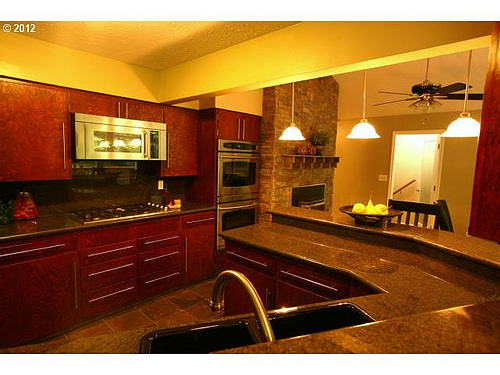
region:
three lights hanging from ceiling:
[282, 83, 490, 143]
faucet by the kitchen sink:
[211, 257, 283, 334]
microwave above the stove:
[65, 106, 177, 161]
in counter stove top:
[63, 198, 195, 223]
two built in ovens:
[195, 139, 263, 251]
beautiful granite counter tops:
[259, 222, 383, 260]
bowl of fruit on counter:
[343, 195, 408, 226]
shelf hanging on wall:
[285, 154, 355, 174]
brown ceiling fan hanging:
[379, 82, 484, 115]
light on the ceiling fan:
[407, 95, 442, 124]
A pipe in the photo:
[208, 268, 275, 336]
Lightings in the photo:
[344, 78, 380, 143]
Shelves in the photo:
[290, 209, 380, 259]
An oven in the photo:
[210, 139, 261, 223]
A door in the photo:
[393, 139, 437, 223]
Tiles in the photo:
[148, 287, 207, 322]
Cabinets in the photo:
[123, 229, 180, 286]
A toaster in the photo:
[8, 186, 41, 223]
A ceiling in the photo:
[160, 23, 227, 74]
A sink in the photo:
[152, 284, 356, 353]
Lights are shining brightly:
[278, 120, 479, 138]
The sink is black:
[147, 302, 372, 354]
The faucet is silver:
[209, 268, 271, 341]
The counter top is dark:
[387, 256, 452, 301]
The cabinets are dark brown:
[6, 209, 215, 342]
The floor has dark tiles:
[110, 282, 224, 331]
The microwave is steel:
[71, 112, 165, 159]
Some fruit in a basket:
[338, 195, 400, 225]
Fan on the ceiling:
[372, 80, 482, 113]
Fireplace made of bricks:
[257, 74, 338, 217]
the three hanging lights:
[277, 48, 474, 140]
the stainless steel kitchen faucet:
[209, 268, 274, 342]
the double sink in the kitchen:
[140, 300, 376, 353]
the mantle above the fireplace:
[283, 152, 339, 169]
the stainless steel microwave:
[73, 113, 167, 160]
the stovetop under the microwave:
[68, 198, 178, 225]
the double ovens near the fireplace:
[216, 135, 262, 250]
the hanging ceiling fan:
[371, 56, 483, 113]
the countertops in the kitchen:
[1, 195, 499, 350]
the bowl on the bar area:
[340, 193, 402, 227]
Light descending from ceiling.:
[281, 122, 303, 142]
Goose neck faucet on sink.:
[209, 271, 282, 342]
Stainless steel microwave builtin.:
[73, 116, 168, 163]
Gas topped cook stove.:
[76, 202, 177, 222]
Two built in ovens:
[217, 137, 260, 239]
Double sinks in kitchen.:
[135, 295, 382, 347]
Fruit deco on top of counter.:
[340, 189, 404, 226]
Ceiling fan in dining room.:
[371, 82, 488, 112]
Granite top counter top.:
[18, 213, 75, 234]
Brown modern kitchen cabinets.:
[86, 217, 216, 310]